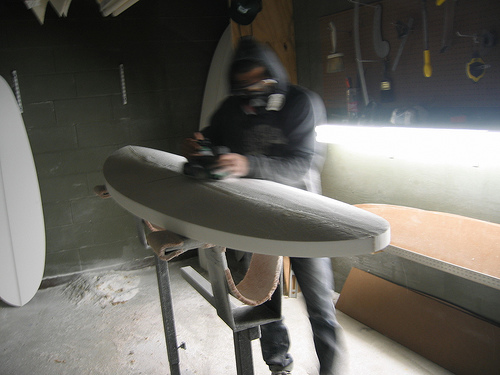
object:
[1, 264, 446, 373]
floor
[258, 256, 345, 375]
pants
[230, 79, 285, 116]
protective mask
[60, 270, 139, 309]
dust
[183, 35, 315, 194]
black hoodie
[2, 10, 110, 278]
block wall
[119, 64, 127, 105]
metal strip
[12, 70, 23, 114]
metal strip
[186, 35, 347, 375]
jacket man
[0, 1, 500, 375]
room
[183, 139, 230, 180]
electric sander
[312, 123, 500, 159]
light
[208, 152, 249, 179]
hand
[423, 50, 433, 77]
handle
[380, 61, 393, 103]
tool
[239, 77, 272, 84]
eyes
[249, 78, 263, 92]
nose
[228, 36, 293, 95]
head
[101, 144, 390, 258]
surfboard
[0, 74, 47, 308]
surfboard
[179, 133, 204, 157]
hands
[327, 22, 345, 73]
tool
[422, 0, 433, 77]
tool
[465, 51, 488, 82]
tool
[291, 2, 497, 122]
wall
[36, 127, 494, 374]
work area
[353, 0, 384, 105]
tool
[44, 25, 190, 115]
wall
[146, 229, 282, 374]
frame